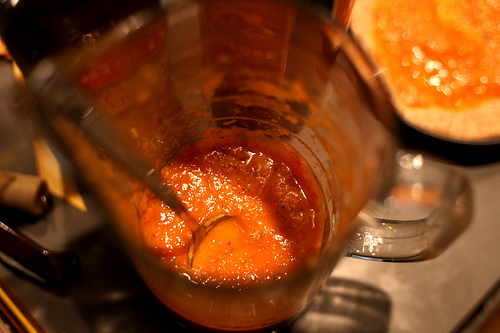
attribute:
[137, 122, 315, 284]
condiment — orange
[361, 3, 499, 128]
food — liquid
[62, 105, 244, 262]
spoon — curved 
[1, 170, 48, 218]
brown handle — small, round, light brown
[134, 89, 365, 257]
dish — glass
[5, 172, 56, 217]
handle — tan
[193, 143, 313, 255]
liquid — orange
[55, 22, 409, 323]
container — glass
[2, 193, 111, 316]
object — black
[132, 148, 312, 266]
food — liquid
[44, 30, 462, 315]
container — glass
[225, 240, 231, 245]
speck — small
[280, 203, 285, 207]
speck — small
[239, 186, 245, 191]
speck — small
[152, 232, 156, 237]
speck — small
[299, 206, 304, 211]
speck — small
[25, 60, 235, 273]
spoon — silver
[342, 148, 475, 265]
handle — glass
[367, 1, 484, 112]
condiment — orange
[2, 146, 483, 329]
surface — dark